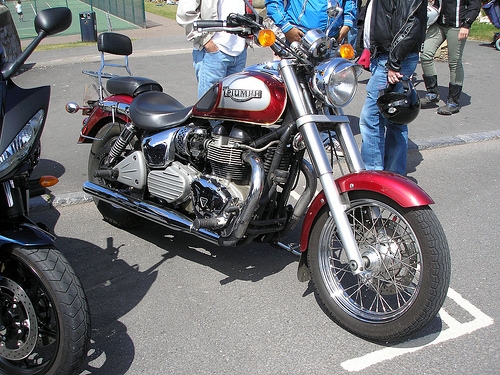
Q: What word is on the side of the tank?
A: Triumph.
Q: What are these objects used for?
A: Transportation.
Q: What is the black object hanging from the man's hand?
A: Helmet.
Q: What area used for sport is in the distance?
A: Tennis court.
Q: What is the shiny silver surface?
A: Chrome.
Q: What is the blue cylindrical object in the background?
A: Trash can.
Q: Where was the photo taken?
A: In a parking lot.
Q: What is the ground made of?
A: Asphalt.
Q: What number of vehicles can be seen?
A: Two.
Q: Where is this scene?
A: In a parking lot.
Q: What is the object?
A: A motorcycle.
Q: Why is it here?
A: Because it is not in use.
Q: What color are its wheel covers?
A: Red.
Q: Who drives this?
A: The owner.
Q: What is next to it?
A: Another motorcycle.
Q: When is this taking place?
A: During the day.